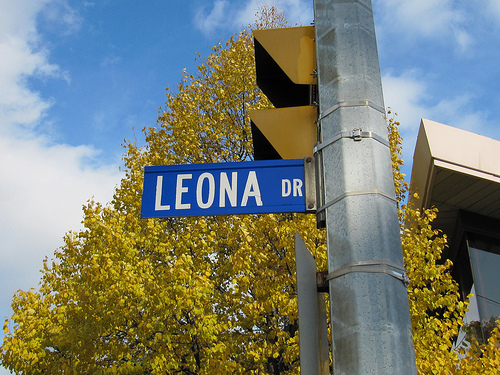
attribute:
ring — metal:
[315, 189, 399, 214]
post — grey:
[313, 1, 414, 373]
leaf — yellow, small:
[1, 315, 13, 332]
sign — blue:
[137, 154, 312, 222]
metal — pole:
[307, 0, 422, 373]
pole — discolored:
[310, 20, 390, 104]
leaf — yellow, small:
[429, 205, 439, 215]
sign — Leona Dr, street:
[138, 147, 313, 224]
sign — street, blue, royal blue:
[137, 160, 308, 215]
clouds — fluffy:
[24, 119, 68, 216]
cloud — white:
[4, 11, 124, 197]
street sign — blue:
[139, 153, 314, 222]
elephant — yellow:
[87, 229, 216, 348]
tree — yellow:
[19, 3, 499, 355]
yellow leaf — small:
[452, 315, 467, 328]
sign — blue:
[126, 147, 383, 223]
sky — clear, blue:
[98, 20, 195, 118]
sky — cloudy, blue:
[0, 1, 496, 118]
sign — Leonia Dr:
[109, 109, 336, 296]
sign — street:
[99, 145, 481, 350]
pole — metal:
[302, 48, 477, 370]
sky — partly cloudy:
[4, 5, 497, 302]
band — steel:
[309, 123, 396, 157]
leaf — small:
[411, 189, 422, 201]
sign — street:
[96, 97, 350, 247]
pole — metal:
[262, 5, 445, 332]